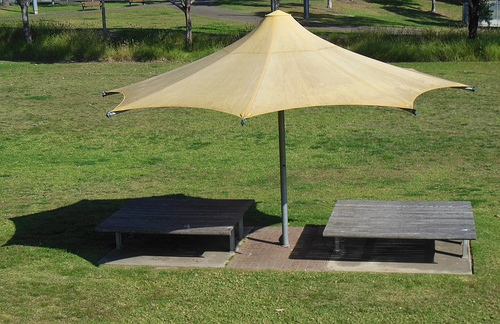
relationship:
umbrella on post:
[101, 8, 471, 126] [276, 110, 290, 244]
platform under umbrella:
[322, 197, 476, 256] [106, 11, 478, 137]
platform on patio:
[322, 197, 476, 256] [94, 223, 474, 276]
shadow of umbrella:
[0, 193, 296, 268] [101, 5, 470, 123]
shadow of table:
[3, 159, 296, 267] [119, 170, 253, 246]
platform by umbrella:
[321, 199, 478, 264] [105, 10, 472, 242]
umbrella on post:
[103, 12, 473, 113] [276, 110, 290, 244]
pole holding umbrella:
[276, 109, 289, 247] [103, 12, 473, 113]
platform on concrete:
[321, 199, 478, 264] [96, 224, 476, 284]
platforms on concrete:
[91, 198, 254, 251] [96, 224, 476, 284]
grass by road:
[1, 24, 497, 64] [199, 1, 262, 33]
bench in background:
[79, 0, 109, 11] [4, 2, 484, 43]